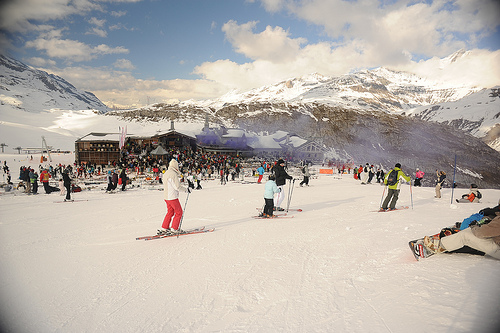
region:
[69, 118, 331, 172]
Sprawled out buildings ski lodge.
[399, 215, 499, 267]
Skateboarder resting sitting snow.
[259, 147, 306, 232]
Parent and child ready to ski.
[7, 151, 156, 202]
Group of people awaiting other skiers.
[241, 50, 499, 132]
White snow capped mountains distance.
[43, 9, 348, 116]
Partially cloudy sky over mountains.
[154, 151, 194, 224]
skier in white colored snow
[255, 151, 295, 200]
skier in white colored snow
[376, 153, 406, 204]
skier in white colored snow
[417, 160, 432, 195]
skier in white colored snow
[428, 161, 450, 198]
skier in white colored snow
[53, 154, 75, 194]
skier in white colored snow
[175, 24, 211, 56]
white clouds in blue sky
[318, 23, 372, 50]
white clouds in blue sky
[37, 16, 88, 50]
white clouds in blue sky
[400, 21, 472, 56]
white clouds in blue sky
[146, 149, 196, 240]
a person taht is sking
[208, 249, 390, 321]
ground covered in snow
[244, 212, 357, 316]
ground covered in white snow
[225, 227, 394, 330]
snow covering the ground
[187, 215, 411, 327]
white snow covering the ground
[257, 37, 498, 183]
snow covering the mountain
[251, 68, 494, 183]
white snow covering the mountain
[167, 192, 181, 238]
a person wearing red pants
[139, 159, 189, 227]
a person wearing jacket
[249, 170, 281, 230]
a person wearing black pants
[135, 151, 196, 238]
skier on hill side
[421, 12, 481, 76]
white clouds in blue sky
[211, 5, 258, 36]
white clouds in blue sky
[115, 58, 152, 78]
white clouds in blue sky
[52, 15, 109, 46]
white clouds in blue sky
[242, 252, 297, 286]
white snow on hill side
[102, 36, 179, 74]
white clouds in blue sky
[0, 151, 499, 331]
a snowy ski slope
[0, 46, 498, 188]
a large mountain range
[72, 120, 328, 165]
a large ski resort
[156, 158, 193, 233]
a person skiing on the snow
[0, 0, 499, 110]
a large area of blue cloudy sky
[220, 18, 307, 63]
a white cloud in the sky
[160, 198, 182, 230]
a skier's red pants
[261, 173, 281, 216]
a child skiing on the snow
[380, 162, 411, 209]
a person skiing on the snow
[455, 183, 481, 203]
a person sitting in the snow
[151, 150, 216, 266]
a person sking on the snow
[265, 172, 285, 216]
a person sking on the snow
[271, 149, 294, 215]
a person sking on the snow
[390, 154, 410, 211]
a person sking on the snow